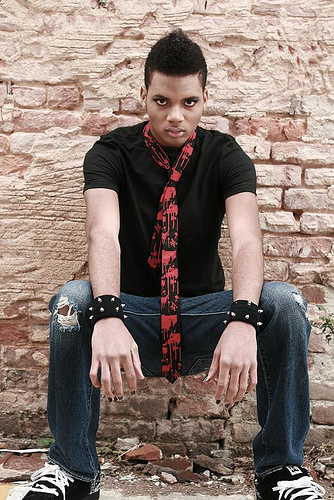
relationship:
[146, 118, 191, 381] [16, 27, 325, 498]
tie on man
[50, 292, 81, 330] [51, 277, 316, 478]
hole in jeans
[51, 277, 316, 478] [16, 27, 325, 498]
jeans on man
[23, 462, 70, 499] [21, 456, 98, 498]
shoe laces on shoe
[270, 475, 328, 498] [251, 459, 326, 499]
shoe laces on shoe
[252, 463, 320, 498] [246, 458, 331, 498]
shoe on feet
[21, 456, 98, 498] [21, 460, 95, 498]
shoe on feet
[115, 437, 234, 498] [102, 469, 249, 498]
bricks on ground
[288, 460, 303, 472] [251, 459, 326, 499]
logo on front of shoe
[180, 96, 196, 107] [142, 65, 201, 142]
liner on face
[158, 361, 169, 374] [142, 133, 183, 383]
spot on tie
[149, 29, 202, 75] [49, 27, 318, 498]
cut on man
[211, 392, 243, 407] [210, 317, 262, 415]
polish on hand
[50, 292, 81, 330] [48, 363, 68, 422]
hole in denim material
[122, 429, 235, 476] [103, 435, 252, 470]
broken bricks on ground